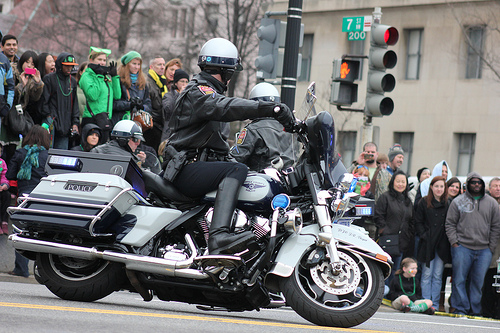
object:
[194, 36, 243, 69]
helmet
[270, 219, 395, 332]
wheel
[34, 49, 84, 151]
people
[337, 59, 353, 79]
hand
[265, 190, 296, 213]
light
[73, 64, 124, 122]
jacket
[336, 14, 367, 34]
sign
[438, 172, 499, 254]
hoodie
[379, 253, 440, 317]
boy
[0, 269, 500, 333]
ground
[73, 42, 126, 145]
girl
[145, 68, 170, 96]
scarf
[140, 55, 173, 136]
man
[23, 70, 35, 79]
phone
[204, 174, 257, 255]
boots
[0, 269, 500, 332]
road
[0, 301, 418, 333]
line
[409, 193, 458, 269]
coat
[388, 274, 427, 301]
sweater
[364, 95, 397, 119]
traffic light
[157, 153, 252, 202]
trouser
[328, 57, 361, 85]
light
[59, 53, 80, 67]
cap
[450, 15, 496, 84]
windows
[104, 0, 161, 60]
trees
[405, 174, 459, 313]
girl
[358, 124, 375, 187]
pole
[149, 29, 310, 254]
police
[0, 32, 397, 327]
motorcycle